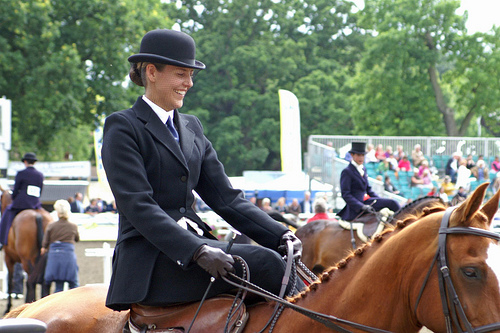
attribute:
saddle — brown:
[129, 300, 230, 332]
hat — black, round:
[129, 28, 210, 74]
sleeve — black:
[95, 117, 192, 262]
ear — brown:
[449, 175, 490, 225]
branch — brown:
[433, 71, 462, 140]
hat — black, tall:
[348, 141, 375, 164]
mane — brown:
[287, 237, 401, 299]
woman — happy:
[99, 40, 290, 312]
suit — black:
[345, 163, 396, 218]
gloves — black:
[199, 243, 231, 278]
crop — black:
[182, 281, 210, 328]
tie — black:
[165, 119, 186, 154]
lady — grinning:
[66, 27, 393, 299]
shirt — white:
[178, 218, 203, 239]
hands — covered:
[192, 230, 339, 283]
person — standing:
[52, 187, 80, 290]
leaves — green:
[244, 29, 326, 91]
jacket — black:
[343, 163, 361, 192]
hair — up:
[118, 63, 153, 97]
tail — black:
[34, 215, 52, 269]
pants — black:
[202, 242, 293, 299]